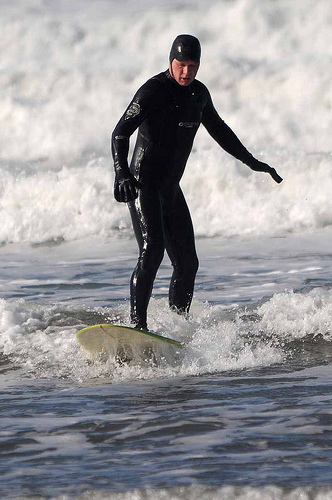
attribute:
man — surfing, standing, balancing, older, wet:
[110, 32, 284, 328]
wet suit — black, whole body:
[110, 88, 284, 331]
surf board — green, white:
[73, 324, 199, 372]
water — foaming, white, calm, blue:
[2, 350, 330, 496]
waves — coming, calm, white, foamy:
[3, 299, 331, 378]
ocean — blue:
[5, 7, 327, 495]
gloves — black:
[239, 154, 288, 188]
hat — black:
[168, 32, 206, 69]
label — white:
[112, 154, 126, 178]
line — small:
[93, 324, 121, 347]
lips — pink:
[180, 74, 193, 86]